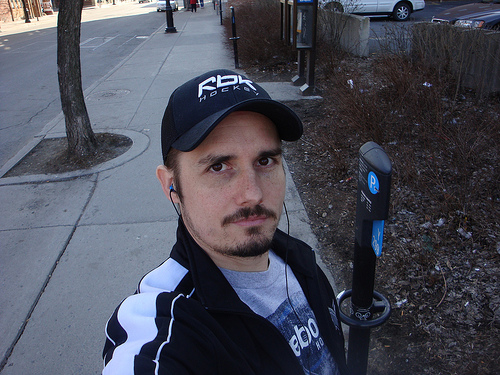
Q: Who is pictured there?
A: A man.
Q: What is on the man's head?
A: Cap.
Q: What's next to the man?
A: Parking meter.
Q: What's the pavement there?
A: Sidewalk.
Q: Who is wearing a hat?
A: A man.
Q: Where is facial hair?
A: On man's face.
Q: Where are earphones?
A: In man's ears.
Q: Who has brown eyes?
A: A man.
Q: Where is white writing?
A: On a hat.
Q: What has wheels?
A: A white car.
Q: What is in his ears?
A: Earbuds.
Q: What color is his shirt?
A: Gray.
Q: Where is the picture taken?
A: On the sidewalk.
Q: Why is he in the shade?
A: The sun is blocked by a building.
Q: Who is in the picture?
A: One man.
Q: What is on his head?
A: A baseball hat.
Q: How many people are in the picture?
A: One.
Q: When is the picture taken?
A: Daytime.